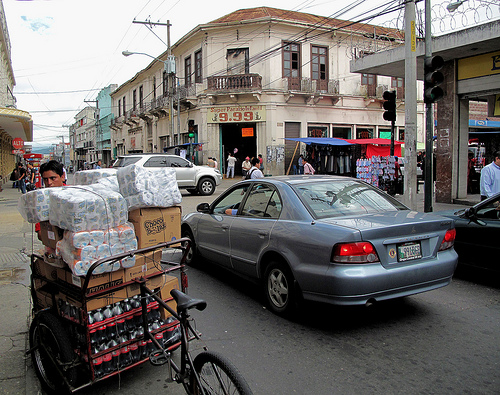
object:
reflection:
[296, 180, 397, 214]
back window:
[291, 179, 411, 219]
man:
[246, 158, 266, 178]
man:
[480, 149, 500, 202]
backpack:
[243, 169, 257, 180]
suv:
[74, 153, 224, 195]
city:
[0, 0, 500, 395]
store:
[199, 105, 424, 180]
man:
[226, 154, 238, 179]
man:
[242, 156, 253, 176]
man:
[233, 148, 240, 160]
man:
[258, 154, 264, 174]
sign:
[208, 105, 267, 123]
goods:
[49, 184, 128, 229]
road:
[0, 178, 500, 395]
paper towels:
[117, 167, 182, 208]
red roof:
[343, 138, 405, 144]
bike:
[26, 238, 253, 395]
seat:
[169, 289, 207, 317]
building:
[96, 84, 118, 167]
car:
[180, 174, 459, 315]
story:
[108, 24, 422, 123]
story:
[111, 105, 423, 177]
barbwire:
[484, 2, 493, 22]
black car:
[425, 191, 499, 274]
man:
[34, 160, 71, 241]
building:
[111, 6, 433, 184]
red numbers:
[219, 113, 228, 121]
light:
[441, 228, 456, 243]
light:
[335, 241, 375, 256]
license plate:
[398, 244, 422, 262]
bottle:
[94, 308, 107, 341]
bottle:
[90, 345, 103, 379]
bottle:
[100, 340, 114, 373]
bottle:
[138, 326, 149, 362]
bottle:
[124, 298, 136, 330]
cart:
[22, 236, 202, 393]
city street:
[177, 174, 498, 393]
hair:
[39, 160, 65, 178]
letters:
[211, 107, 215, 112]